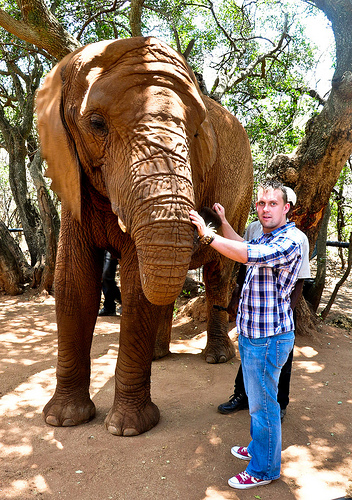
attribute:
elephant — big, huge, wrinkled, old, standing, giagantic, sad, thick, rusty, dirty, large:
[30, 28, 265, 438]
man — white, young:
[191, 176, 315, 481]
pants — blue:
[230, 327, 292, 474]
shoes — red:
[208, 445, 273, 496]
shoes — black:
[213, 395, 301, 430]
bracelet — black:
[194, 229, 217, 248]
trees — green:
[1, 3, 350, 263]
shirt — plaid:
[223, 221, 309, 325]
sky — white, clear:
[19, 12, 350, 100]